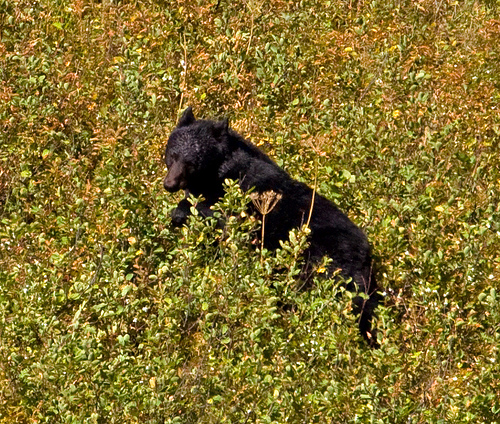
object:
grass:
[0, 0, 500, 424]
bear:
[162, 105, 383, 351]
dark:
[163, 105, 379, 353]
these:
[64, 96, 153, 322]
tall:
[28, 154, 84, 199]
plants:
[0, 0, 499, 424]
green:
[0, 0, 500, 424]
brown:
[0, 369, 64, 424]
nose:
[164, 181, 175, 192]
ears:
[176, 106, 229, 135]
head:
[163, 124, 222, 192]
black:
[160, 105, 380, 349]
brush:
[0, 0, 499, 424]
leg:
[171, 197, 231, 261]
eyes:
[171, 152, 194, 167]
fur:
[163, 105, 384, 349]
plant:
[0, 300, 4, 424]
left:
[212, 117, 230, 142]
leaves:
[0, 0, 500, 424]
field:
[0, 0, 500, 424]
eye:
[169, 151, 179, 159]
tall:
[240, 312, 264, 355]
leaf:
[477, 292, 487, 301]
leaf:
[201, 301, 209, 311]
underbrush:
[0, 0, 500, 424]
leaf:
[415, 73, 425, 80]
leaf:
[20, 166, 32, 178]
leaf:
[115, 334, 131, 347]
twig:
[249, 189, 284, 265]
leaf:
[364, 374, 370, 387]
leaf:
[56, 395, 68, 411]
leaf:
[151, 93, 156, 108]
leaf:
[273, 389, 280, 398]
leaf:
[326, 386, 333, 394]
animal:
[162, 103, 380, 349]